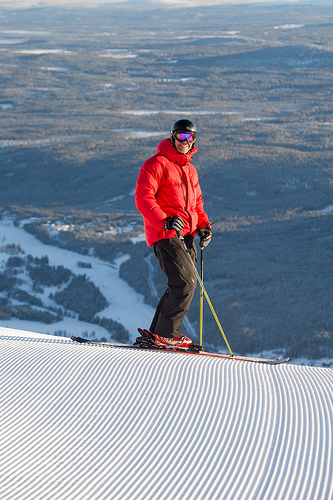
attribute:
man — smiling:
[117, 116, 225, 356]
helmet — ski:
[169, 117, 197, 144]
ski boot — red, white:
[150, 328, 198, 355]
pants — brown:
[156, 242, 199, 318]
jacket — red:
[135, 138, 210, 247]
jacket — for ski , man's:
[148, 139, 207, 240]